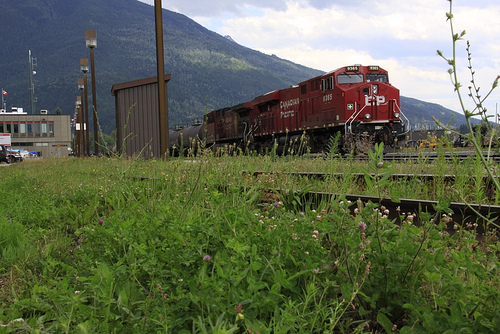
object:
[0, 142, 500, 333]
grass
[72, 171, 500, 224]
tracks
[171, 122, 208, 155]
truck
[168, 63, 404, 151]
train